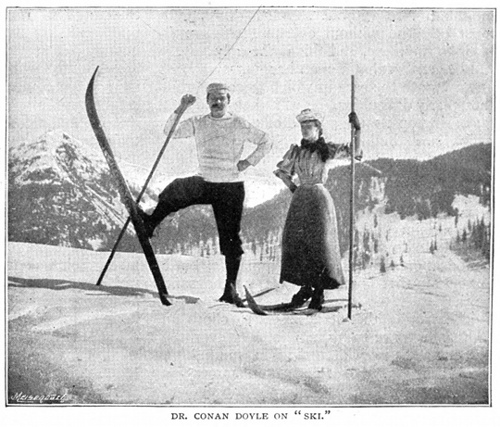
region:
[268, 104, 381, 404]
A woman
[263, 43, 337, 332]
A woman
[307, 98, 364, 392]
A woman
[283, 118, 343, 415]
A woman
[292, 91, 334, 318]
A woman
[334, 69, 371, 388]
A woman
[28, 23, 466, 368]
black and white ski photo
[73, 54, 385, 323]
a couple skiing together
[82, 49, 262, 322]
the man looks happy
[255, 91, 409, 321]
the woman is enjoying herself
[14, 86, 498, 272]
mountains in the background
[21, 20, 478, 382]
it seems like a clear and sunny day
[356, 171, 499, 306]
trees along the horizen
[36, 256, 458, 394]
bright, white snow covered ground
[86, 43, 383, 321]
playing out in the snow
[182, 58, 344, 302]
a couple in love in the snow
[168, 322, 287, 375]
The ground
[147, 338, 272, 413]
The ground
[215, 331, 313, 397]
The ground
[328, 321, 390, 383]
The ground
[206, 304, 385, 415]
The ground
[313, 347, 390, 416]
The ground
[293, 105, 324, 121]
The hat the lady is wearing.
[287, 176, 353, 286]
The long skirt the lady is wearing.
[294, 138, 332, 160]
The scarf around the lady's neck.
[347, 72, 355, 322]
The ski pole in the lady's hand.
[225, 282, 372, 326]
The skis the lady is wearing.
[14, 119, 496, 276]
The mountains in the background.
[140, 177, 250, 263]
The black pants the man is wearing.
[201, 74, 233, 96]
The hat the man is wearing.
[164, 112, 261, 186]
The white shirt the man is wearing.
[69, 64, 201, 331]
The ski on the man's foot that is in the air.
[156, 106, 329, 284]
A couple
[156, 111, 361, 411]
A couple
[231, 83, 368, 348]
A couple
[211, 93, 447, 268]
A couple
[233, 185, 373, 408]
A couple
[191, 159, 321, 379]
A couple